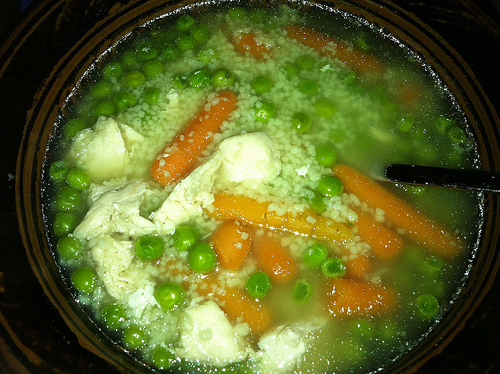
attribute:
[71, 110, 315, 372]
pasta — small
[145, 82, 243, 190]
carrot — orange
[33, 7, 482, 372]
soup — white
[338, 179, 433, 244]
carrot — baby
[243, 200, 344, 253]
carrot — baby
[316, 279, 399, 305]
carrot — baby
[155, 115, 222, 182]
carrot — baby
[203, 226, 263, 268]
carrot — baby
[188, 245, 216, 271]
pea — green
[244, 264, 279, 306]
pea — green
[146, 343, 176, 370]
pea — green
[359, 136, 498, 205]
spoon — black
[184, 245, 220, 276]
pea — big, green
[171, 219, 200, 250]
pea — big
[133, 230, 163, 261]
pea — green, big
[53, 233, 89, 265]
pea — green, big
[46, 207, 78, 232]
pea — green, big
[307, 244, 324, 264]
peas — dented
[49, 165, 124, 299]
peas — green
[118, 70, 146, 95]
pea — green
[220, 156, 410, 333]
carrots — whole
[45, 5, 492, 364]
broth — chicken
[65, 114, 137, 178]
chunk — white